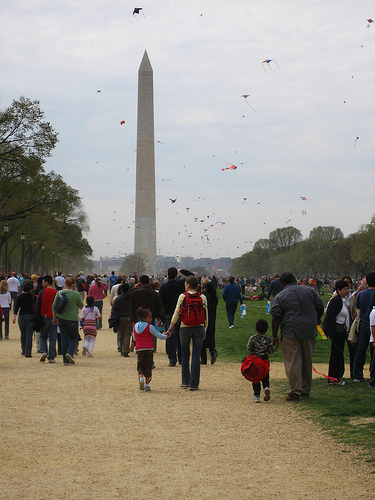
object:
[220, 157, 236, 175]
kites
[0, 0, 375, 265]
sky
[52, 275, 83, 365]
people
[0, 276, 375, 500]
walkway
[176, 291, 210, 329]
backpack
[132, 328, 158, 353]
vest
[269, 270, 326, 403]
man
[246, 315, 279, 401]
kid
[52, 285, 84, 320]
blouse